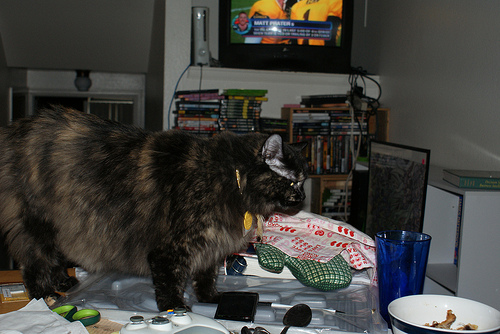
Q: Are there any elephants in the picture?
A: No, there are no elephants.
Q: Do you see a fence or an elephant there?
A: No, there are no elephants or fences.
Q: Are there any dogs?
A: No, there are no dogs.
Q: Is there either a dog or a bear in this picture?
A: No, there are no dogs or bears.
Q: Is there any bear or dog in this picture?
A: No, there are no dogs or bears.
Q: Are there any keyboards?
A: No, there are no keyboards.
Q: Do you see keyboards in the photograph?
A: No, there are no keyboards.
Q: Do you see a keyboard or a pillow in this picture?
A: No, there are no keyboards or pillows.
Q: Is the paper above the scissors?
A: Yes, the paper is above the scissors.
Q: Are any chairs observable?
A: No, there are no chairs.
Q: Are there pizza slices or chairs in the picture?
A: No, there are no chairs or pizza slices.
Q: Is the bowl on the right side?
A: Yes, the bowl is on the right of the image.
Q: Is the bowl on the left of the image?
A: No, the bowl is on the right of the image.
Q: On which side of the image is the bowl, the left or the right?
A: The bowl is on the right of the image.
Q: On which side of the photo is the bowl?
A: The bowl is on the right of the image.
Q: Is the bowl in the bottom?
A: Yes, the bowl is in the bottom of the image.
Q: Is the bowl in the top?
A: No, the bowl is in the bottom of the image.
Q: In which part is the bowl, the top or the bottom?
A: The bowl is in the bottom of the image.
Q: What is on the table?
A: The bowl is on the table.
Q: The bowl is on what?
A: The bowl is on the table.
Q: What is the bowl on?
A: The bowl is on the table.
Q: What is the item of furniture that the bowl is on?
A: The piece of furniture is a table.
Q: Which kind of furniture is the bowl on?
A: The bowl is on the table.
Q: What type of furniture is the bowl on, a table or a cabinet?
A: The bowl is on a table.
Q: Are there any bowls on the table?
A: Yes, there is a bowl on the table.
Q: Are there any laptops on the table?
A: No, there is a bowl on the table.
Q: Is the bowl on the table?
A: Yes, the bowl is on the table.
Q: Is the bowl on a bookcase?
A: No, the bowl is on the table.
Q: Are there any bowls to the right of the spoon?
A: Yes, there is a bowl to the right of the spoon.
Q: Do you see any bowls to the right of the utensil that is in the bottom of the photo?
A: Yes, there is a bowl to the right of the spoon.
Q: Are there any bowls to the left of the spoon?
A: No, the bowl is to the right of the spoon.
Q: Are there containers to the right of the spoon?
A: No, there is a bowl to the right of the spoon.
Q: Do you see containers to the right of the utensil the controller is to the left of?
A: No, there is a bowl to the right of the spoon.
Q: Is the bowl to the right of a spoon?
A: Yes, the bowl is to the right of a spoon.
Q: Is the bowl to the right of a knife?
A: No, the bowl is to the right of a spoon.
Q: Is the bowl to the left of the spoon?
A: No, the bowl is to the right of the spoon.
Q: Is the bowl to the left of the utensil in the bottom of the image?
A: No, the bowl is to the right of the spoon.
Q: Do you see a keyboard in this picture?
A: No, there are no keyboards.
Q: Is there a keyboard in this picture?
A: No, there are no keyboards.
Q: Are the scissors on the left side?
A: Yes, the scissors are on the left of the image.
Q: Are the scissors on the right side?
A: No, the scissors are on the left of the image.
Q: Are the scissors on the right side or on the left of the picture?
A: The scissors are on the left of the image.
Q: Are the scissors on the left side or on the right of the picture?
A: The scissors are on the left of the image.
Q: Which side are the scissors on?
A: The scissors are on the left of the image.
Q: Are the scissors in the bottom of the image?
A: Yes, the scissors are in the bottom of the image.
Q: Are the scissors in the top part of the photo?
A: No, the scissors are in the bottom of the image.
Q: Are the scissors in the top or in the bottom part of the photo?
A: The scissors are in the bottom of the image.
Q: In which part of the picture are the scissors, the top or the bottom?
A: The scissors are in the bottom of the image.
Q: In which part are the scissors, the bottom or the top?
A: The scissors are in the bottom of the image.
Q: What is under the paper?
A: The scissors are under the paper.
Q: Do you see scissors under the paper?
A: Yes, there are scissors under the paper.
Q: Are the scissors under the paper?
A: Yes, the scissors are under the paper.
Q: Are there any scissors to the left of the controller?
A: Yes, there are scissors to the left of the controller.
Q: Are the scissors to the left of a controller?
A: Yes, the scissors are to the left of a controller.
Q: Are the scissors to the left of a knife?
A: No, the scissors are to the left of a controller.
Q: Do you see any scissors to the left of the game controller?
A: Yes, there are scissors to the left of the game controller.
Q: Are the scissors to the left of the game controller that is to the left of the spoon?
A: Yes, the scissors are to the left of the game controller.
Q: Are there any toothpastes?
A: No, there are no toothpastes.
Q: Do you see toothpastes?
A: No, there are no toothpastes.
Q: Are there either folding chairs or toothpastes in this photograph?
A: No, there are no toothpastes or folding chairs.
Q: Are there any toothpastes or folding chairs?
A: No, there are no toothpastes or folding chairs.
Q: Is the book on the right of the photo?
A: Yes, the book is on the right of the image.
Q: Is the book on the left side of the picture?
A: No, the book is on the right of the image.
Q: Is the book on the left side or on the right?
A: The book is on the right of the image.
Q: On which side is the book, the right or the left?
A: The book is on the right of the image.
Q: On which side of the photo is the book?
A: The book is on the right of the image.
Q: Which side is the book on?
A: The book is on the right of the image.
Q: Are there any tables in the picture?
A: Yes, there is a table.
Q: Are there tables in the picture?
A: Yes, there is a table.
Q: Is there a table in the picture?
A: Yes, there is a table.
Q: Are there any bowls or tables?
A: Yes, there is a table.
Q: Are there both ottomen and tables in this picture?
A: No, there is a table but no ottomen.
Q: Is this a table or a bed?
A: This is a table.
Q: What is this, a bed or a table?
A: This is a table.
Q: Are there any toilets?
A: No, there are no toilets.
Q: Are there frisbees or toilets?
A: No, there are no toilets or frisbees.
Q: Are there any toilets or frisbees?
A: No, there are no toilets or frisbees.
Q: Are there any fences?
A: No, there are no fences.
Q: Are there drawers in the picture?
A: No, there are no drawers.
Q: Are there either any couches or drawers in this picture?
A: No, there are no drawers or couches.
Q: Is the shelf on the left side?
A: No, the shelf is on the right of the image.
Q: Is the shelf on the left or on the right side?
A: The shelf is on the right of the image.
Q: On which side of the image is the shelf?
A: The shelf is on the right of the image.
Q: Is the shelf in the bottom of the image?
A: Yes, the shelf is in the bottom of the image.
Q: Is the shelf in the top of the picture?
A: No, the shelf is in the bottom of the image.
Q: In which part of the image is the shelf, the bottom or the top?
A: The shelf is in the bottom of the image.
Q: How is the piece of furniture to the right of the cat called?
A: The piece of furniture is a shelf.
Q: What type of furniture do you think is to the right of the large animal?
A: The piece of furniture is a shelf.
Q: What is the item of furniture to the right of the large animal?
A: The piece of furniture is a shelf.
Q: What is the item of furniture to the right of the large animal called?
A: The piece of furniture is a shelf.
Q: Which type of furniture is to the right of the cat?
A: The piece of furniture is a shelf.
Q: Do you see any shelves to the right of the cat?
A: Yes, there is a shelf to the right of the cat.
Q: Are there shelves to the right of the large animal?
A: Yes, there is a shelf to the right of the cat.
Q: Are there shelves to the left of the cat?
A: No, the shelf is to the right of the cat.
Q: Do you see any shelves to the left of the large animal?
A: No, the shelf is to the right of the cat.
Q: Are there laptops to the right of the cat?
A: No, there is a shelf to the right of the cat.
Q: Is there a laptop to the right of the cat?
A: No, there is a shelf to the right of the cat.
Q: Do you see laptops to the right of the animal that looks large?
A: No, there is a shelf to the right of the cat.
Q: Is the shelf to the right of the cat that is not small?
A: Yes, the shelf is to the right of the cat.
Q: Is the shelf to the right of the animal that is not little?
A: Yes, the shelf is to the right of the cat.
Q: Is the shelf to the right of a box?
A: No, the shelf is to the right of the cat.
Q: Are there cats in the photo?
A: Yes, there is a cat.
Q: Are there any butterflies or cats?
A: Yes, there is a cat.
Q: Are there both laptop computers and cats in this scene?
A: No, there is a cat but no laptops.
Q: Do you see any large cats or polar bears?
A: Yes, there is a large cat.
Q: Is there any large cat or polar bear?
A: Yes, there is a large cat.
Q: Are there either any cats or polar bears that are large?
A: Yes, the cat is large.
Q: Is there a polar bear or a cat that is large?
A: Yes, the cat is large.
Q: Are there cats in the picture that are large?
A: Yes, there is a large cat.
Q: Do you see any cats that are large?
A: Yes, there is a cat that is large.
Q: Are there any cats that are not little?
A: Yes, there is a large cat.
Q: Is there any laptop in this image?
A: No, there are no laptops.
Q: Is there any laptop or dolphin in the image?
A: No, there are no laptops or dolphins.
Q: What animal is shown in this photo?
A: The animal is a cat.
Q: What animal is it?
A: The animal is a cat.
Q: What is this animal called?
A: This is a cat.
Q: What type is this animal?
A: This is a cat.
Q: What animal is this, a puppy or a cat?
A: This is a cat.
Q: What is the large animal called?
A: The animal is a cat.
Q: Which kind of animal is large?
A: The animal is a cat.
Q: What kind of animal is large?
A: The animal is a cat.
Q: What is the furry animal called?
A: The animal is a cat.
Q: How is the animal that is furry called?
A: The animal is a cat.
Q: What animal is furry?
A: The animal is a cat.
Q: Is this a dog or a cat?
A: This is a cat.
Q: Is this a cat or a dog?
A: This is a cat.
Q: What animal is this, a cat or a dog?
A: This is a cat.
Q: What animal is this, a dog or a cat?
A: This is a cat.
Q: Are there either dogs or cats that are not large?
A: No, there is a cat but it is large.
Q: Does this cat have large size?
A: Yes, the cat is large.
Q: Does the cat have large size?
A: Yes, the cat is large.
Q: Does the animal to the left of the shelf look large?
A: Yes, the cat is large.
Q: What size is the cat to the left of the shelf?
A: The cat is large.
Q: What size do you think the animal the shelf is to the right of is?
A: The cat is large.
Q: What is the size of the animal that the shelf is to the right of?
A: The cat is large.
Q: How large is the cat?
A: The cat is large.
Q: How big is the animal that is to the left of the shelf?
A: The cat is large.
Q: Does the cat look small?
A: No, the cat is large.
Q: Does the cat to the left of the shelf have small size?
A: No, the cat is large.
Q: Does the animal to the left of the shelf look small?
A: No, the cat is large.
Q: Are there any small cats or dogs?
A: No, there is a cat but it is large.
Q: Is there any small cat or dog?
A: No, there is a cat but it is large.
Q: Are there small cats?
A: No, there is a cat but it is large.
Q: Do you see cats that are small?
A: No, there is a cat but it is large.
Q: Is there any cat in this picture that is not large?
A: No, there is a cat but it is large.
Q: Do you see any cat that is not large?
A: No, there is a cat but it is large.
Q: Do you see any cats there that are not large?
A: No, there is a cat but it is large.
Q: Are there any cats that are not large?
A: No, there is a cat but it is large.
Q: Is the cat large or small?
A: The cat is large.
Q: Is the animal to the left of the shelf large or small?
A: The cat is large.